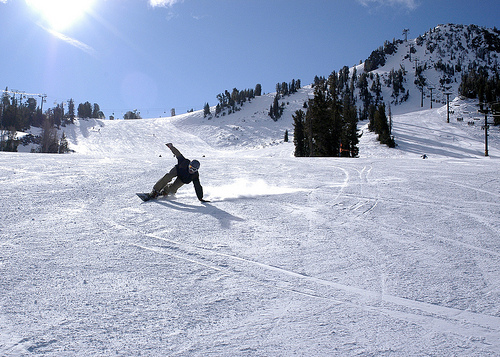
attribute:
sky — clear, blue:
[7, 8, 380, 97]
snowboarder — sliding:
[147, 143, 217, 201]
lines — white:
[298, 169, 427, 300]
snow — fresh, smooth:
[8, 32, 492, 349]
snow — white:
[1, 63, 497, 351]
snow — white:
[4, 94, 494, 350]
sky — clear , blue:
[0, 4, 498, 117]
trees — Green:
[292, 84, 361, 154]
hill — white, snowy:
[14, 22, 498, 347]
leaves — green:
[307, 96, 341, 140]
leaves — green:
[314, 98, 348, 148]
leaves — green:
[380, 110, 390, 132]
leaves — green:
[275, 77, 337, 172]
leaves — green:
[261, 85, 289, 125]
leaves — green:
[449, 55, 488, 119]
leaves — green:
[58, 60, 112, 142]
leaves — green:
[42, 85, 90, 136]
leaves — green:
[352, 9, 422, 93]